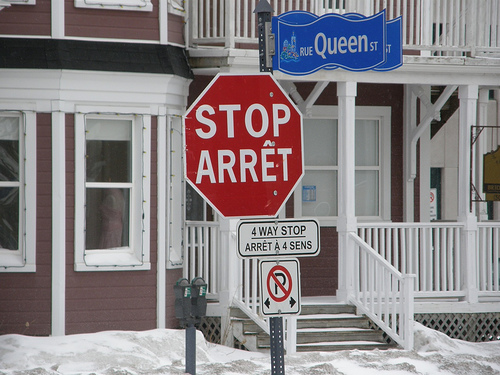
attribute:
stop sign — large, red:
[184, 79, 317, 224]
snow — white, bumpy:
[31, 313, 450, 359]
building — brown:
[9, 20, 500, 332]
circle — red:
[266, 266, 289, 304]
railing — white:
[247, 227, 407, 321]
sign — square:
[426, 184, 444, 219]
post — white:
[331, 92, 354, 299]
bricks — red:
[71, 12, 146, 38]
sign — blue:
[276, 2, 404, 78]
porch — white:
[365, 74, 492, 297]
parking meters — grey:
[180, 278, 221, 317]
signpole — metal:
[245, 1, 274, 72]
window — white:
[69, 118, 151, 272]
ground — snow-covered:
[16, 334, 181, 373]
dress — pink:
[98, 183, 127, 242]